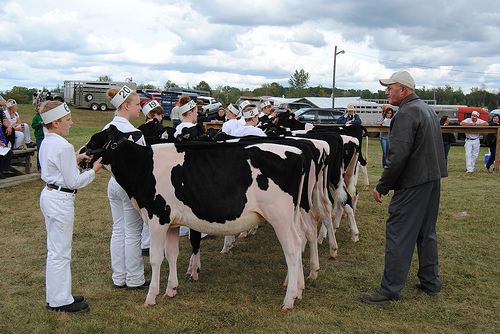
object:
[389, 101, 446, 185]
jacket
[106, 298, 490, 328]
grass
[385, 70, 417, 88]
cap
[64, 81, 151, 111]
vehicle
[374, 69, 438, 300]
man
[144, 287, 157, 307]
hoofs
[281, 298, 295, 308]
hoofs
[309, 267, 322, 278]
hoofs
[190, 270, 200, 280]
hoofs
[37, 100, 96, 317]
boy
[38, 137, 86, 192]
shirt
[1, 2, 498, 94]
cloud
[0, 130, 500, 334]
ground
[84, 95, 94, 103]
wheel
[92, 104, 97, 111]
wheel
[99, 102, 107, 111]
wheel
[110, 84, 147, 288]
girl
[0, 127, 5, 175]
person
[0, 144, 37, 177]
stand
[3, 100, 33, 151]
person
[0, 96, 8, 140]
person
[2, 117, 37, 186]
bleachers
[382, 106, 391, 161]
woman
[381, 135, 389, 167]
blue jeans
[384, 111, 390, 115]
sunglasses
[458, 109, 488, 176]
man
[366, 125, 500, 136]
table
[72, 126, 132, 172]
head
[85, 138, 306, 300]
cow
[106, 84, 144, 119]
head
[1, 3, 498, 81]
sky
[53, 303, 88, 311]
shoe